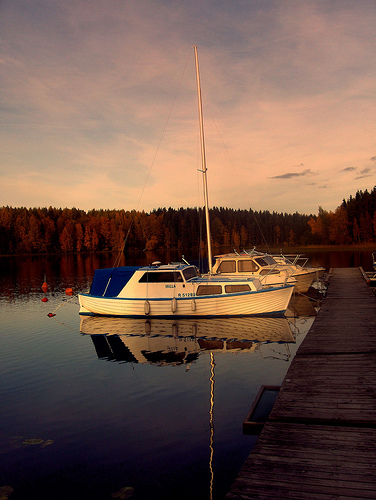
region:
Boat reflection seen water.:
[63, 305, 299, 364]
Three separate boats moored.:
[74, 252, 329, 337]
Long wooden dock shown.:
[316, 258, 375, 429]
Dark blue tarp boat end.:
[71, 261, 140, 322]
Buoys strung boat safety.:
[139, 280, 203, 325]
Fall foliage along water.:
[2, 199, 196, 253]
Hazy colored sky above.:
[11, 47, 168, 175]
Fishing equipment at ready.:
[33, 275, 95, 326]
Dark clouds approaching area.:
[265, 154, 375, 196]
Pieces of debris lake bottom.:
[7, 429, 145, 477]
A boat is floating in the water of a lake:
[75, 261, 294, 324]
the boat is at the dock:
[226, 262, 375, 497]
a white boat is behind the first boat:
[205, 246, 324, 296]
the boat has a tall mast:
[187, 44, 220, 274]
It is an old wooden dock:
[207, 266, 372, 498]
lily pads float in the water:
[20, 433, 58, 451]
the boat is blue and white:
[79, 260, 292, 322]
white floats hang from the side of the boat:
[141, 295, 199, 316]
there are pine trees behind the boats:
[3, 184, 374, 248]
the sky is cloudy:
[1, 0, 374, 213]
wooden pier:
[207, 275, 336, 488]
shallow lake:
[78, 335, 304, 465]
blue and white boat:
[57, 254, 329, 333]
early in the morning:
[46, 171, 367, 233]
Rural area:
[36, 206, 374, 266]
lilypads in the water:
[17, 429, 170, 484]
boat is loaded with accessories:
[132, 266, 306, 291]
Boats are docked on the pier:
[221, 252, 351, 320]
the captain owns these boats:
[64, 237, 319, 318]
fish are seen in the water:
[11, 350, 253, 483]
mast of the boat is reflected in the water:
[209, 350, 215, 497]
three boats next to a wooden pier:
[223, 263, 375, 497]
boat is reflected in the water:
[78, 315, 296, 367]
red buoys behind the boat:
[63, 287, 73, 296]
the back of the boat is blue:
[91, 265, 141, 296]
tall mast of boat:
[193, 42, 216, 275]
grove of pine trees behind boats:
[0, 205, 309, 250]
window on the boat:
[195, 284, 221, 295]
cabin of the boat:
[89, 261, 259, 296]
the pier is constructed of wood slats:
[248, 452, 374, 472]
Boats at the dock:
[71, 242, 342, 352]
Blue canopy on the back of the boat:
[87, 259, 155, 315]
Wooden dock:
[247, 251, 375, 470]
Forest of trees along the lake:
[7, 188, 365, 252]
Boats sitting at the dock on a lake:
[14, 136, 374, 459]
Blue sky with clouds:
[9, 15, 357, 190]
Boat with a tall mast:
[72, 25, 301, 340]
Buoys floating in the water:
[32, 269, 81, 321]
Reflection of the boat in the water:
[75, 305, 305, 372]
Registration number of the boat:
[172, 287, 200, 307]